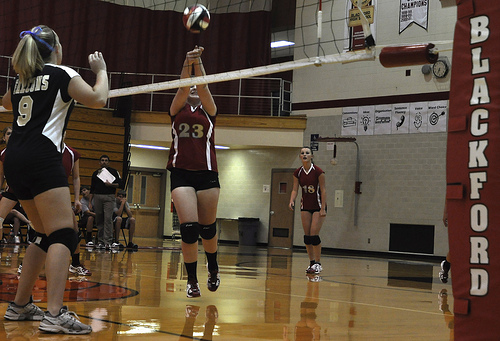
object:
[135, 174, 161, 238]
door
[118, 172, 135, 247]
door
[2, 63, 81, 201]
uniform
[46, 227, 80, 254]
pad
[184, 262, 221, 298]
sneakers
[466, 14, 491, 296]
letters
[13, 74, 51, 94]
letters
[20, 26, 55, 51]
ribbon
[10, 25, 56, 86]
hair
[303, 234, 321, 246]
knee pad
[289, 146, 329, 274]
female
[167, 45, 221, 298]
female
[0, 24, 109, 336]
female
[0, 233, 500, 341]
court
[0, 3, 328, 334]
basketball game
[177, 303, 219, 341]
shadow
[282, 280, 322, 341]
shadow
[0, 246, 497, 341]
floor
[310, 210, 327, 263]
leg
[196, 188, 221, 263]
leg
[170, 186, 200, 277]
leg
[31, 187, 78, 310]
leg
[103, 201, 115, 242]
leg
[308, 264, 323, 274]
sneaker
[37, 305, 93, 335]
sneaker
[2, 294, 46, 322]
sneaker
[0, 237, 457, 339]
shiny wood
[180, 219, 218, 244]
knee pads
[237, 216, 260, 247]
metal trash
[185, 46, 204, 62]
hands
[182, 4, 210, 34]
ball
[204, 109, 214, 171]
stripe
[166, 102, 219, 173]
shirt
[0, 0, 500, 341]
blackford gym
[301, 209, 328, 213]
shorts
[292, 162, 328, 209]
top